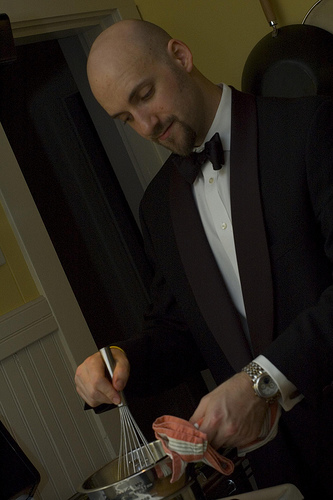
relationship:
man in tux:
[75, 17, 330, 499] [116, 84, 331, 498]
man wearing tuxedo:
[75, 17, 330, 499] [116, 84, 331, 498]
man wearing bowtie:
[75, 17, 330, 499] [177, 131, 224, 183]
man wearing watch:
[75, 17, 330, 499] [243, 359, 283, 406]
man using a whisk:
[75, 17, 330, 499] [99, 343, 163, 481]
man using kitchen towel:
[75, 17, 330, 499] [151, 415, 233, 483]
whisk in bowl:
[99, 343, 163, 481] [82, 437, 187, 499]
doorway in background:
[1, 0, 262, 499] [2, 0, 333, 301]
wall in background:
[140, 0, 332, 100] [2, 0, 333, 301]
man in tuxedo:
[75, 17, 330, 499] [116, 84, 331, 498]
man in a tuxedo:
[75, 17, 330, 499] [116, 84, 331, 498]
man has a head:
[75, 17, 330, 499] [87, 18, 221, 156]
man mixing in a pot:
[75, 17, 330, 499] [82, 437, 187, 499]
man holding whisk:
[75, 17, 330, 499] [99, 343, 163, 481]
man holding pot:
[75, 17, 330, 499] [82, 437, 187, 499]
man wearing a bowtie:
[75, 17, 330, 499] [177, 131, 224, 183]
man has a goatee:
[75, 17, 330, 499] [152, 115, 196, 158]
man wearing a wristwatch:
[75, 17, 330, 499] [243, 359, 283, 406]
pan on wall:
[239, 1, 330, 95] [140, 0, 332, 100]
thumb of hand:
[113, 350, 129, 392] [75, 345, 130, 406]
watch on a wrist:
[243, 359, 283, 406] [243, 353, 301, 422]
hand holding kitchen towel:
[191, 360, 280, 453] [151, 415, 233, 483]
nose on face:
[136, 110, 157, 134] [88, 73, 197, 155]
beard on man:
[152, 115, 196, 158] [75, 17, 330, 499]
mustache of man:
[141, 116, 177, 140] [75, 17, 330, 499]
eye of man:
[132, 84, 155, 102] [75, 17, 330, 499]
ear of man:
[168, 38, 196, 74] [75, 17, 330, 499]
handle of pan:
[258, 0, 282, 33] [239, 1, 330, 95]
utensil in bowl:
[99, 343, 163, 481] [82, 437, 187, 499]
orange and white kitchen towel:
[152, 413, 210, 439] [151, 415, 233, 483]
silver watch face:
[243, 359, 283, 406] [254, 371, 277, 398]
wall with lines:
[140, 0, 332, 100] [0, 127, 141, 500]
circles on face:
[264, 377, 272, 385] [254, 371, 277, 398]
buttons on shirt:
[206, 171, 232, 234] [176, 83, 251, 319]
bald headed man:
[66, 19, 169, 79] [75, 17, 330, 499]